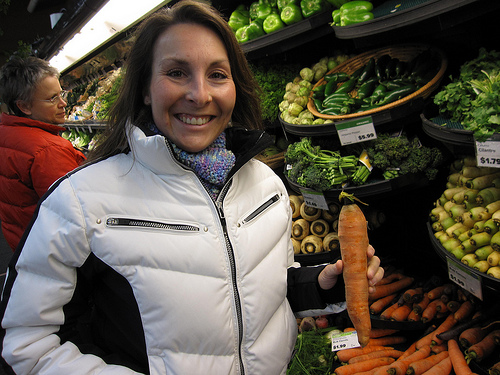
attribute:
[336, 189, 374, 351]
carrot — orange, long, numerous, for sale, inside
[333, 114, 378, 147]
sign — white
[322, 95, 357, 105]
pepper — green, displayed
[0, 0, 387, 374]
woman — smiling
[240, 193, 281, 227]
zipper — metal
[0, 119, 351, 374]
jacket — white, orange, puffy, thick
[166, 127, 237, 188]
scarf — blue, multi-colored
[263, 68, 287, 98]
lettuce — green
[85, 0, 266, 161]
hair — short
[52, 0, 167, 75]
light — above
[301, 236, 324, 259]
turnip — black